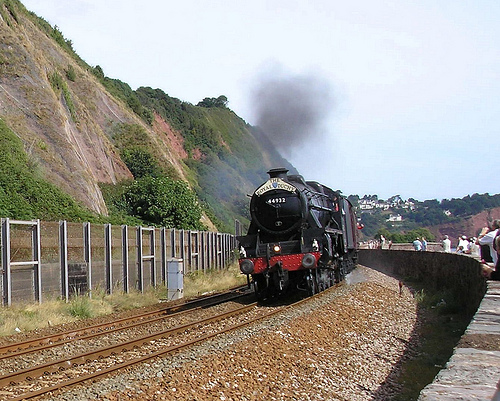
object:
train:
[235, 166, 363, 304]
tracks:
[0, 298, 303, 400]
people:
[440, 215, 500, 256]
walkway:
[414, 277, 499, 400]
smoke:
[249, 144, 333, 339]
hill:
[29, 105, 134, 198]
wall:
[0, 218, 40, 307]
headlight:
[267, 241, 285, 254]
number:
[263, 196, 289, 205]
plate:
[238, 254, 319, 268]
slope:
[307, 317, 368, 384]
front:
[237, 178, 313, 301]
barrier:
[56, 224, 131, 296]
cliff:
[166, 133, 206, 192]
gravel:
[221, 346, 264, 377]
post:
[80, 222, 93, 296]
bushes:
[126, 186, 157, 206]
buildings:
[357, 193, 404, 210]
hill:
[416, 217, 447, 238]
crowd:
[436, 233, 471, 255]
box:
[164, 257, 183, 299]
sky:
[440, 113, 464, 153]